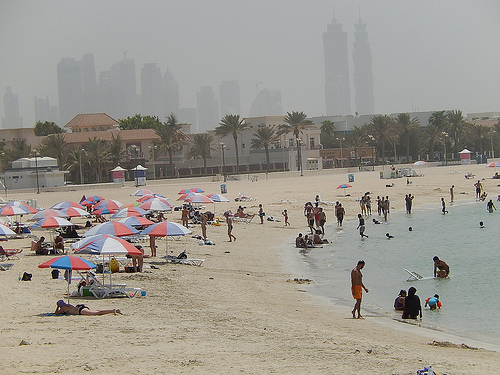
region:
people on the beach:
[20, 181, 363, 323]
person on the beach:
[327, 250, 383, 325]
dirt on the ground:
[173, 286, 259, 361]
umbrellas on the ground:
[48, 172, 210, 318]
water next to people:
[418, 225, 460, 250]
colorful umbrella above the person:
[41, 251, 93, 278]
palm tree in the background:
[209, 111, 254, 167]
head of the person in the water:
[469, 215, 491, 235]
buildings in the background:
[43, 42, 363, 205]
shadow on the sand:
[36, 302, 55, 330]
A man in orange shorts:
[351, 257, 373, 320]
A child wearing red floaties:
[422, 292, 444, 312]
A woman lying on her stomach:
[46, 298, 125, 318]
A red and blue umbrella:
[37, 250, 99, 315]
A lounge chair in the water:
[398, 265, 441, 284]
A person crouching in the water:
[428, 255, 451, 278]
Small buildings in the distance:
[109, 163, 148, 189]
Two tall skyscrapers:
[321, 5, 377, 117]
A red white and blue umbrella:
[71, 235, 141, 293]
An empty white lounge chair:
[161, 253, 206, 267]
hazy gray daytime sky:
[0, 2, 497, 109]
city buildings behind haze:
[0, 8, 377, 126]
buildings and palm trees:
[1, 106, 498, 174]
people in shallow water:
[294, 192, 495, 351]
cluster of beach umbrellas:
[0, 181, 232, 318]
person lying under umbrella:
[40, 251, 120, 317]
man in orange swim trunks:
[349, 260, 369, 319]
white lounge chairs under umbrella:
[75, 233, 140, 300]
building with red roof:
[57, 126, 159, 176]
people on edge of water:
[292, 190, 349, 262]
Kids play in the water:
[386, 283, 443, 325]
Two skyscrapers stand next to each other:
[323, 7, 380, 118]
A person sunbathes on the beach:
[51, 296, 125, 318]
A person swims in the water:
[475, 218, 485, 230]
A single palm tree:
[215, 116, 250, 173]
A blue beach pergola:
[131, 163, 151, 186]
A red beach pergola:
[113, 164, 128, 190]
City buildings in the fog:
[6, 3, 388, 113]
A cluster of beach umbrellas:
[3, 185, 220, 277]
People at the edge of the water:
[293, 231, 330, 250]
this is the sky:
[200, 16, 292, 61]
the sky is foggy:
[161, 18, 289, 60]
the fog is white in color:
[226, 17, 303, 64]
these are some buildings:
[26, 14, 474, 153]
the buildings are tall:
[36, 23, 394, 108]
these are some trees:
[146, 109, 483, 152]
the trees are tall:
[156, 120, 475, 166]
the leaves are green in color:
[287, 112, 302, 122]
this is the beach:
[31, 182, 494, 360]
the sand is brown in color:
[188, 332, 253, 366]